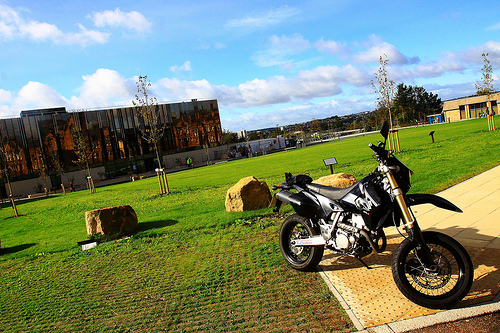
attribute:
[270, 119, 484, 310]
motorcycle — black, painted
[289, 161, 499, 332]
sidewalk — yellow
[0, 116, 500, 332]
grass — trimmed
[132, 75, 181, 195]
thin tree — planted, standing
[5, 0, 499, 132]
sky — cloudy, blue